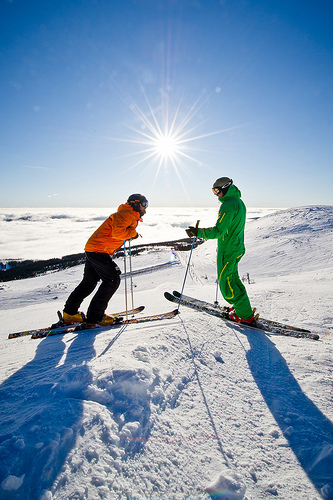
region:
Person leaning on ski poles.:
[56, 181, 149, 328]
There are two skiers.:
[84, 175, 271, 338]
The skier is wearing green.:
[191, 193, 256, 315]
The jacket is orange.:
[81, 207, 142, 248]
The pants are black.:
[70, 255, 119, 314]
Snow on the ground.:
[14, 350, 331, 493]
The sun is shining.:
[132, 116, 201, 174]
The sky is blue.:
[5, 2, 328, 93]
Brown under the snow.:
[0, 232, 203, 283]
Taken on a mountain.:
[10, 209, 330, 499]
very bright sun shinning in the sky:
[124, 101, 215, 179]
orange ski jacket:
[80, 202, 144, 253]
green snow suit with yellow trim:
[197, 185, 260, 318]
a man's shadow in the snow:
[225, 327, 332, 498]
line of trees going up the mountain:
[3, 254, 74, 278]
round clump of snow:
[201, 466, 254, 498]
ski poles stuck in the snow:
[120, 238, 140, 326]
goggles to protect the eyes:
[206, 182, 237, 195]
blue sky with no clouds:
[10, 11, 117, 138]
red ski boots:
[217, 304, 265, 328]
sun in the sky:
[123, 115, 196, 164]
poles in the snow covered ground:
[116, 236, 140, 319]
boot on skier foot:
[59, 308, 85, 320]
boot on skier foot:
[83, 310, 117, 325]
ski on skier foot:
[33, 305, 189, 337]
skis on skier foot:
[161, 277, 328, 339]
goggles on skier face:
[209, 185, 223, 194]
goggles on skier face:
[136, 196, 151, 205]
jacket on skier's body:
[83, 202, 135, 250]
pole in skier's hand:
[171, 219, 200, 300]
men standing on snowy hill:
[10, 76, 330, 431]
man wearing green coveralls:
[179, 164, 267, 317]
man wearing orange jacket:
[79, 196, 146, 261]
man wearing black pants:
[67, 242, 134, 330]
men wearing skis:
[11, 169, 321, 362]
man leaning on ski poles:
[0, 192, 181, 340]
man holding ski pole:
[158, 171, 294, 347]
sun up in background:
[15, 84, 330, 209]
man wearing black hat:
[116, 181, 154, 220]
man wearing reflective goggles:
[207, 177, 239, 199]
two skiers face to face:
[5, 170, 325, 380]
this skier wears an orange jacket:
[78, 194, 155, 252]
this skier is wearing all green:
[207, 172, 269, 331]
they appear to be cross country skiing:
[8, 180, 320, 364]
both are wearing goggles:
[114, 170, 237, 219]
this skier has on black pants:
[56, 244, 124, 332]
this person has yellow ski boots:
[57, 297, 121, 332]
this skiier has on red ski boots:
[223, 303, 254, 325]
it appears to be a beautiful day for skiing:
[37, 110, 304, 493]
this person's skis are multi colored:
[7, 305, 177, 345]